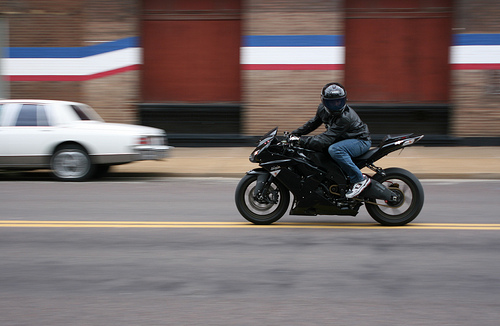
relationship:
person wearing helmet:
[275, 69, 432, 203] [319, 79, 350, 111]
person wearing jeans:
[275, 69, 432, 203] [327, 131, 373, 176]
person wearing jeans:
[275, 69, 432, 203] [328, 136, 371, 186]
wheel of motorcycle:
[362, 167, 422, 228] [229, 115, 433, 225]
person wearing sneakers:
[275, 69, 432, 203] [340, 173, 376, 201]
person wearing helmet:
[275, 69, 432, 203] [315, 82, 351, 115]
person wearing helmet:
[275, 69, 432, 203] [319, 82, 348, 117]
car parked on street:
[0, 95, 179, 183] [0, 175, 499, 325]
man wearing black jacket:
[288, 77, 387, 199] [292, 107, 375, 152]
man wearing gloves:
[288, 77, 387, 199] [295, 137, 308, 146]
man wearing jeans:
[288, 77, 387, 199] [320, 146, 360, 185]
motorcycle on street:
[227, 119, 438, 233] [28, 178, 467, 324]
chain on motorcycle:
[317, 165, 409, 210] [217, 118, 449, 225]